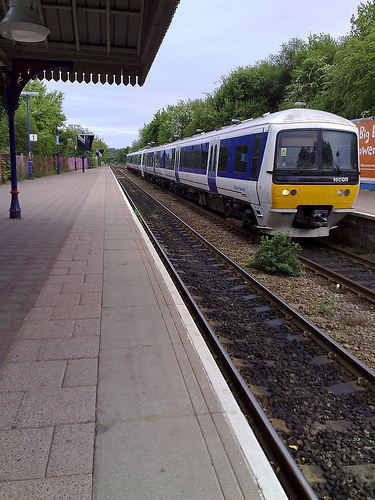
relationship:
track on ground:
[110, 162, 374, 499] [2, 164, 373, 498]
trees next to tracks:
[18, 86, 88, 154] [107, 167, 372, 492]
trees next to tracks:
[131, 1, 375, 146] [107, 167, 372, 492]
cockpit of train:
[261, 112, 361, 232] [126, 105, 364, 238]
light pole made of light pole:
[22, 93, 37, 178] [26, 93, 34, 180]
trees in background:
[131, 1, 370, 146] [38, 77, 244, 164]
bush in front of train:
[246, 230, 301, 276] [126, 105, 364, 238]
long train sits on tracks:
[125, 102, 362, 241] [124, 162, 363, 356]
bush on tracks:
[251, 230, 301, 282] [191, 301, 317, 364]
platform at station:
[0, 163, 277, 497] [3, 26, 274, 499]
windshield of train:
[271, 125, 363, 188] [126, 105, 364, 238]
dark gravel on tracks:
[123, 180, 342, 498] [297, 241, 374, 287]